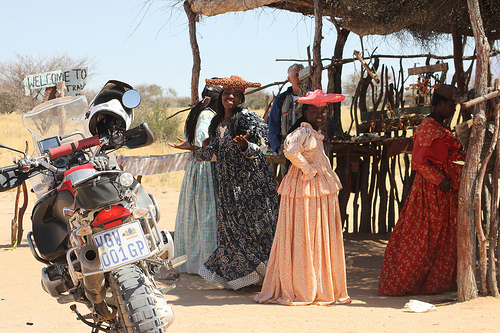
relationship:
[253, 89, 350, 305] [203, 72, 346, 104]
woman wearing hats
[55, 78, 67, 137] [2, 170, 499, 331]
post in road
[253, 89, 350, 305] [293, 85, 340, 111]
woman wearing hat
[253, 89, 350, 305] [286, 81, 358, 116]
woman wearing hat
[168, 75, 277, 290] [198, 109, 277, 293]
woman wearing dress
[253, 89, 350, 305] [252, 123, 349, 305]
woman wearing dress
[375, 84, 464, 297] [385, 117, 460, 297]
woman wearing dress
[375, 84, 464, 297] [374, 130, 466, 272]
woman wearing dress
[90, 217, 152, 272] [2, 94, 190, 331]
license plate on motorcycle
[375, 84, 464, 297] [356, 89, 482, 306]
woman wearing red dress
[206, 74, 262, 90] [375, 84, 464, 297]
hat on woman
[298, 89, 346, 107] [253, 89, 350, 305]
hats on woman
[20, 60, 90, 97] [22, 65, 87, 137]
sign on post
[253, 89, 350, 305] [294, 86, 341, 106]
woman had hat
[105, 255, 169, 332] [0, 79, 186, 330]
tire of a cycle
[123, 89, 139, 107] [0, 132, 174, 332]
mirror on a cycle